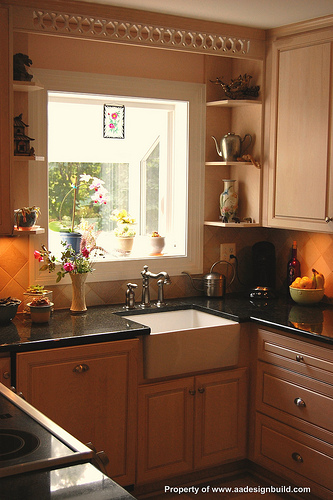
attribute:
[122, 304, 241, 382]
sink — white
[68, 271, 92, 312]
vase — white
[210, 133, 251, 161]
teapot — sitting, silver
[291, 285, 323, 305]
bowl — white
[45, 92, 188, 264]
window — large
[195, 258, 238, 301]
watering can — metal, silver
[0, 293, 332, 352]
counter — black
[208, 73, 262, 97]
plant — withered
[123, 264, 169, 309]
faucet — metal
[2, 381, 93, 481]
stove — metallic